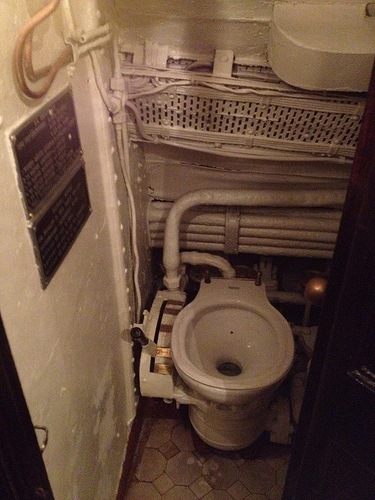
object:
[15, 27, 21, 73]
orange paint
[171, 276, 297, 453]
toilet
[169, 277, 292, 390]
bowl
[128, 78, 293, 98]
wires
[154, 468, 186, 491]
brown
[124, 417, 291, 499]
floor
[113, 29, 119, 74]
pipe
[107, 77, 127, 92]
fitting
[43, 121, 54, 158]
copper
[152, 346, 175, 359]
plate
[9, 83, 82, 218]
plaque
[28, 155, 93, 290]
sign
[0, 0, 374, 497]
bathroom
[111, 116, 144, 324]
wires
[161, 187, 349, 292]
pipe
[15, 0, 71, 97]
pipe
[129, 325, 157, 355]
handle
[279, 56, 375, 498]
door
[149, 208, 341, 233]
pipes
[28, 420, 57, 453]
handle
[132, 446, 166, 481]
tile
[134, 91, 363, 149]
screen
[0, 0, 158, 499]
wall